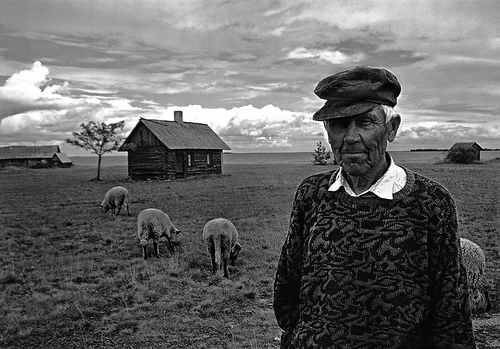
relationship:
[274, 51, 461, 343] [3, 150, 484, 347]
man in field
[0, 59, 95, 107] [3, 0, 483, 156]
cloud in sky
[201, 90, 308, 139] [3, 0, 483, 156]
cloud in sky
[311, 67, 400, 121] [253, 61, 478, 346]
cap on man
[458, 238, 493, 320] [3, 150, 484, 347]
sheep grazing in field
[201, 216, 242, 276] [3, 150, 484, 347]
animal grazing in field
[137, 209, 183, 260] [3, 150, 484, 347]
sheep grazing in field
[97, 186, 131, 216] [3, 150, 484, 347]
sheep grazing in field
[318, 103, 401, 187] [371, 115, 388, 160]
face has wrinkles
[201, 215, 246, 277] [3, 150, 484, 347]
animal on field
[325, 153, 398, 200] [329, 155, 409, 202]
collar on shirt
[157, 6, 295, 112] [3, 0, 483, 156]
cloud in sky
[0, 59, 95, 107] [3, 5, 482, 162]
cloud in distance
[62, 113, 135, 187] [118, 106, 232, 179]
tree next to house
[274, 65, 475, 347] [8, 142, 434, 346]
man in field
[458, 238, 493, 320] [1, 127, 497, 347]
sheep in field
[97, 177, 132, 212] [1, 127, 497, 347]
sheep in field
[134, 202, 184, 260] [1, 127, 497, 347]
sheep in field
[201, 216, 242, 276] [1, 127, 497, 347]
animal in field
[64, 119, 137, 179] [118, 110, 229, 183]
tree near building